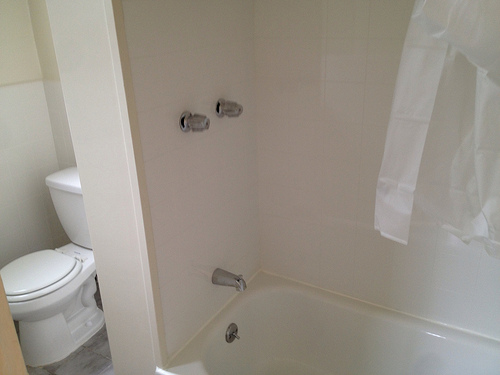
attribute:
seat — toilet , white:
[10, 264, 85, 305]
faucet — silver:
[209, 265, 248, 293]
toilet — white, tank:
[14, 170, 102, 373]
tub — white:
[155, 272, 497, 372]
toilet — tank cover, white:
[0, 166, 127, 368]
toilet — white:
[0, 165, 105, 370]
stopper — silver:
[222, 320, 247, 345]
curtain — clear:
[373, 0, 482, 244]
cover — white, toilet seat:
[28, 275, 70, 299]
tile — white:
[48, 349, 112, 374]